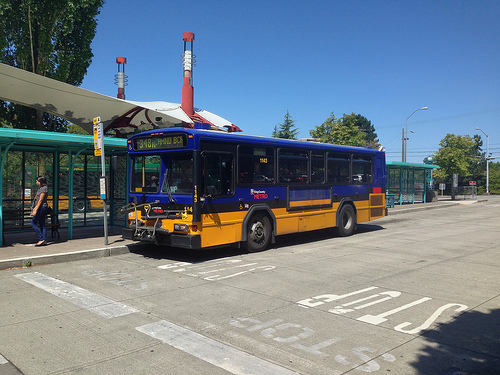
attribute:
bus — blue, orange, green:
[126, 121, 408, 249]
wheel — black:
[241, 213, 272, 252]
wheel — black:
[332, 204, 355, 241]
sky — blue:
[231, 12, 275, 35]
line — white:
[53, 268, 112, 319]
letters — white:
[299, 272, 426, 340]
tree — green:
[10, 16, 81, 62]